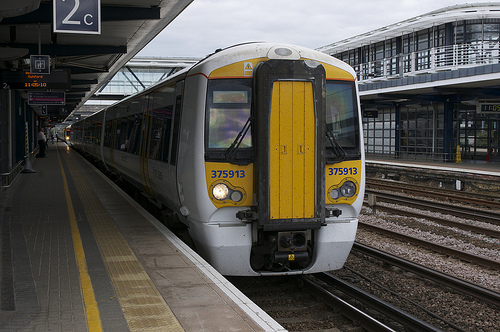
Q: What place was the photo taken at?
A: It was taken at the station.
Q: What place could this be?
A: It is a station.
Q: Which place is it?
A: It is a station.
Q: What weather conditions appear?
A: It is overcast.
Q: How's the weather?
A: It is overcast.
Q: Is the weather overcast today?
A: Yes, it is overcast.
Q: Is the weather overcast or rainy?
A: It is overcast.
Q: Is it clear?
A: No, it is overcast.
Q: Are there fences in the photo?
A: No, there are no fences.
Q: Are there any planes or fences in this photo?
A: No, there are no fences or planes.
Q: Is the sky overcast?
A: Yes, the sky is overcast.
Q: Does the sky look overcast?
A: Yes, the sky is overcast.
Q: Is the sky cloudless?
A: No, the sky is overcast.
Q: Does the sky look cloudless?
A: No, the sky is overcast.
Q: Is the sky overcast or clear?
A: The sky is overcast.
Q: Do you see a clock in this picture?
A: No, there are no clocks.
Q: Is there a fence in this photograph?
A: No, there are no fences.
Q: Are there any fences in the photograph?
A: No, there are no fences.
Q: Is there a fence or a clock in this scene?
A: No, there are no fences or clocks.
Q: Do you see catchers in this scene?
A: No, there are no catchers.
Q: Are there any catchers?
A: No, there are no catchers.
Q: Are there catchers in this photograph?
A: No, there are no catchers.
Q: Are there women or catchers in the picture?
A: No, there are no catchers or women.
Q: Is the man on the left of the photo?
A: Yes, the man is on the left of the image.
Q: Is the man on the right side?
A: No, the man is on the left of the image.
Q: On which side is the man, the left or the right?
A: The man is on the left of the image.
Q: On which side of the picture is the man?
A: The man is on the left of the image.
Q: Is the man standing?
A: Yes, the man is standing.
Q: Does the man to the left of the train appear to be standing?
A: Yes, the man is standing.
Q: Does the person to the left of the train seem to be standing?
A: Yes, the man is standing.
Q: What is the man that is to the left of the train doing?
A: The man is standing.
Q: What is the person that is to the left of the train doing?
A: The man is standing.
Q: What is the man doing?
A: The man is standing.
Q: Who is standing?
A: The man is standing.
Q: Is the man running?
A: No, the man is standing.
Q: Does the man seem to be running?
A: No, the man is standing.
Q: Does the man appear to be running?
A: No, the man is standing.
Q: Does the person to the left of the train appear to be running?
A: No, the man is standing.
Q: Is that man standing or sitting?
A: The man is standing.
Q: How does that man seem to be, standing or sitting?
A: The man is standing.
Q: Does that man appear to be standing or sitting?
A: The man is standing.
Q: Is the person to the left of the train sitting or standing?
A: The man is standing.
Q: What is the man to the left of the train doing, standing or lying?
A: The man is standing.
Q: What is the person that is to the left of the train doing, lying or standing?
A: The man is standing.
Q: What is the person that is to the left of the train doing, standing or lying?
A: The man is standing.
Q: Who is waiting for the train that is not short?
A: The man is waiting for the train.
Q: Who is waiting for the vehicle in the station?
A: The man is waiting for the train.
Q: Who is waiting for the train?
A: The man is waiting for the train.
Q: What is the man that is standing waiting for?
A: The man is waiting for the train.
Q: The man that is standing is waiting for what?
A: The man is waiting for the train.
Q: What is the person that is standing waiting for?
A: The man is waiting for the train.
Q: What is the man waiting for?
A: The man is waiting for the train.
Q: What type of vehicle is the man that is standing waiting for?
A: The man is waiting for the train.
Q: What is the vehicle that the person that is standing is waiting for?
A: The vehicle is a train.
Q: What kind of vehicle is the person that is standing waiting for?
A: The man is waiting for the train.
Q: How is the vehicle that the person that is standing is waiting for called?
A: The vehicle is a train.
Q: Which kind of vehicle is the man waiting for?
A: The man is waiting for the train.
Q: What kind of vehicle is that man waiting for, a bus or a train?
A: The man is waiting for a train.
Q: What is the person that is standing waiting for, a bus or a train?
A: The man is waiting for a train.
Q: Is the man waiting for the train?
A: Yes, the man is waiting for the train.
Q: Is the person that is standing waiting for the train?
A: Yes, the man is waiting for the train.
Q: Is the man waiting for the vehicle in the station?
A: Yes, the man is waiting for the train.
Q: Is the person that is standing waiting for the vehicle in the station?
A: Yes, the man is waiting for the train.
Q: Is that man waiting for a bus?
A: No, the man is waiting for the train.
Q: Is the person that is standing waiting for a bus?
A: No, the man is waiting for the train.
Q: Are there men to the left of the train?
A: Yes, there is a man to the left of the train.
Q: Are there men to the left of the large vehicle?
A: Yes, there is a man to the left of the train.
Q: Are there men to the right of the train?
A: No, the man is to the left of the train.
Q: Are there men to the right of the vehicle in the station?
A: No, the man is to the left of the train.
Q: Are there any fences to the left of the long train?
A: No, there is a man to the left of the train.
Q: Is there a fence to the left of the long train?
A: No, there is a man to the left of the train.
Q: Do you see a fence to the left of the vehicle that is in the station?
A: No, there is a man to the left of the train.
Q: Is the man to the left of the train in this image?
A: Yes, the man is to the left of the train.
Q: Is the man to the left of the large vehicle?
A: Yes, the man is to the left of the train.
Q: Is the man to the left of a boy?
A: No, the man is to the left of the train.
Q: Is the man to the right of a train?
A: No, the man is to the left of a train.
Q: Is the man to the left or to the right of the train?
A: The man is to the left of the train.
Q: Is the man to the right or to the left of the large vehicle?
A: The man is to the left of the train.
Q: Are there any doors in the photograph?
A: Yes, there is a door.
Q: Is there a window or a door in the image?
A: Yes, there is a door.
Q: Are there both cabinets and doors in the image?
A: No, there is a door but no cabinets.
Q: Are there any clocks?
A: No, there are no clocks.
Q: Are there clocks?
A: No, there are no clocks.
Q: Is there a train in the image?
A: Yes, there is a train.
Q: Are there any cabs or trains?
A: Yes, there is a train.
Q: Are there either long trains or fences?
A: Yes, there is a long train.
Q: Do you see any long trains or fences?
A: Yes, there is a long train.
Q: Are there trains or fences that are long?
A: Yes, the train is long.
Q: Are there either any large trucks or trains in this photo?
A: Yes, there is a large train.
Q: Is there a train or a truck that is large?
A: Yes, the train is large.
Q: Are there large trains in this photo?
A: Yes, there is a large train.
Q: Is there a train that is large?
A: Yes, there is a train that is large.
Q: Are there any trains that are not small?
A: Yes, there is a large train.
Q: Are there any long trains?
A: Yes, there is a long train.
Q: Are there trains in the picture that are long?
A: Yes, there is a train that is long.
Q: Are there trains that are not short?
A: Yes, there is a long train.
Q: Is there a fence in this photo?
A: No, there are no fences.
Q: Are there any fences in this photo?
A: No, there are no fences.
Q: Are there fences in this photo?
A: No, there are no fences.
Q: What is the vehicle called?
A: The vehicle is a train.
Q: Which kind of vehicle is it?
A: The vehicle is a train.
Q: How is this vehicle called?
A: This is a train.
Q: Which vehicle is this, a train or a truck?
A: This is a train.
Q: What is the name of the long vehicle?
A: The vehicle is a train.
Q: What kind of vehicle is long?
A: The vehicle is a train.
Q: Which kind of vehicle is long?
A: The vehicle is a train.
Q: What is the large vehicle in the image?
A: The vehicle is a train.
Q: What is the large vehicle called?
A: The vehicle is a train.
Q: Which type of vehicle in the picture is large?
A: The vehicle is a train.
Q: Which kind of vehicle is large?
A: The vehicle is a train.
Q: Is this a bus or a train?
A: This is a train.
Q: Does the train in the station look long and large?
A: Yes, the train is long and large.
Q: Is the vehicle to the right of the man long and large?
A: Yes, the train is long and large.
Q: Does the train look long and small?
A: No, the train is long but large.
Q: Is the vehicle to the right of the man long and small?
A: No, the train is long but large.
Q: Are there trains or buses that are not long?
A: No, there is a train but it is long.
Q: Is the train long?
A: Yes, the train is long.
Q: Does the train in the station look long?
A: Yes, the train is long.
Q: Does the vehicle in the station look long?
A: Yes, the train is long.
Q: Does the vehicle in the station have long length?
A: Yes, the train is long.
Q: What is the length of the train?
A: The train is long.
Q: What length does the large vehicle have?
A: The train has long length.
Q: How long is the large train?
A: The train is long.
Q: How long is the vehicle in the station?
A: The train is long.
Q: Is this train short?
A: No, the train is long.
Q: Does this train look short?
A: No, the train is long.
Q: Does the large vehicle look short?
A: No, the train is long.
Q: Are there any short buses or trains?
A: No, there is a train but it is long.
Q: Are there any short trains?
A: No, there is a train but it is long.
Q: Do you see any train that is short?
A: No, there is a train but it is long.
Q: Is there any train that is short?
A: No, there is a train but it is long.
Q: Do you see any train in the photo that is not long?
A: No, there is a train but it is long.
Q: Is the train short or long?
A: The train is long.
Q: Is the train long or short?
A: The train is long.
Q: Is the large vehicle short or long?
A: The train is long.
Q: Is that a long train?
A: Yes, that is a long train.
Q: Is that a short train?
A: No, that is a long train.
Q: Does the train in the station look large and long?
A: Yes, the train is large and long.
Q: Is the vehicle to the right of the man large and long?
A: Yes, the train is large and long.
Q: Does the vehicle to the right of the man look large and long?
A: Yes, the train is large and long.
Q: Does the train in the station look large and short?
A: No, the train is large but long.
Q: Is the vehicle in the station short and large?
A: No, the train is large but long.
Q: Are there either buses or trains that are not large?
A: No, there is a train but it is large.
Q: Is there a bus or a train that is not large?
A: No, there is a train but it is large.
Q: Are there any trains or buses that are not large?
A: No, there is a train but it is large.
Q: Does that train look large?
A: Yes, the train is large.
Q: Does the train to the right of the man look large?
A: Yes, the train is large.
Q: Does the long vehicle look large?
A: Yes, the train is large.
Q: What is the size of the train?
A: The train is large.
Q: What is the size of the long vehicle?
A: The train is large.